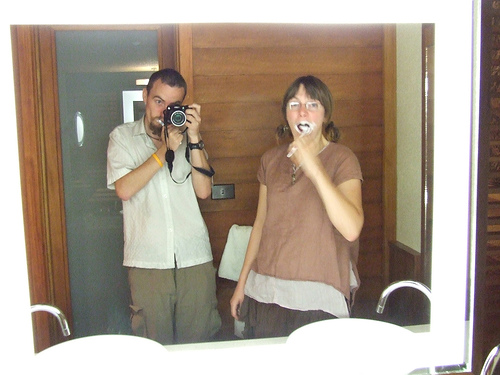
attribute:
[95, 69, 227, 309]
man — taking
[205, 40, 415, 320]
wall — brown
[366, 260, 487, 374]
faucet — silver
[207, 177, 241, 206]
thermometer — silver, black